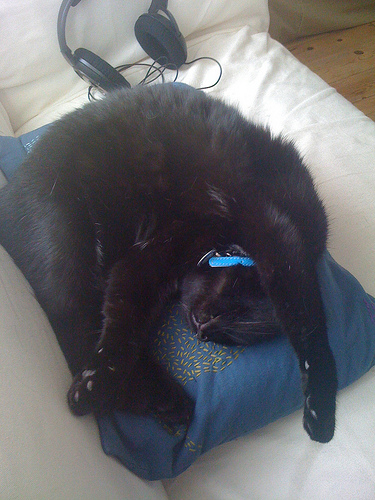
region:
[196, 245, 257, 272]
the blue collar on the cat's neck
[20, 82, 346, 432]
the black cat laying on the pillow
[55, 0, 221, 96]
the headphones sitting on the couch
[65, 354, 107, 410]
a paw of the cat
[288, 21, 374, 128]
the floor by the couch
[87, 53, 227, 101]
the wires attached to the headphones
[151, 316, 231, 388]
the yellow pattern on the pillow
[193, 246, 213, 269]
the tag on the collar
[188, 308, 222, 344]
the mouth and nose of the kitty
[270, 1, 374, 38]
a rug on the floor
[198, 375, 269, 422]
blue pillow that cat is laying on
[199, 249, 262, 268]
blue collar cat is wearing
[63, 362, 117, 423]
paws of the cat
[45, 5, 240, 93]
black headphones on the bed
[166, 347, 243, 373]
decoration on the pillow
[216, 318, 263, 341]
whiskers on the cat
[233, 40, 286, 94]
white sheet on the bed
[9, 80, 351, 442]
black cat laying on the pillow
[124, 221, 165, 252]
white hairs on the cat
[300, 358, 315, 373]
claw on the cat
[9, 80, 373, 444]
a kitty on a pillow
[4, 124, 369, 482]
the pillow is blue with yellow stitching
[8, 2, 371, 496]
white sheets are on the bed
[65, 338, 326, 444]
the cat has black pads on the paws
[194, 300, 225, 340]
the cat's canine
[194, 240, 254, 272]
the cat has a blue collar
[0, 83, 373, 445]
the kitty has all black fur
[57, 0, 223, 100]
a head set is on the bed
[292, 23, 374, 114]
the floor in the room is wooden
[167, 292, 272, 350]
the cat's whiskers are black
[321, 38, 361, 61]
this is the floor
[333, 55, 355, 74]
the floor is wooden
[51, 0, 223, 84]
these are some headphones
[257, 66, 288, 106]
this is a bed sheet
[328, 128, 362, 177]
the sheet is white in color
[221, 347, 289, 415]
this is a pillow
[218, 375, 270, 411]
the pillow is blue in color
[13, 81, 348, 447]
this is a cat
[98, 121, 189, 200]
the fur is black in color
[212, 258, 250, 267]
the collar is blue in color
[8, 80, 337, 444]
an upside down kitty cat on a pillow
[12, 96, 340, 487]
the cat is on a blue pillow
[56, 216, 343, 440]
the kitty is sleeping soundly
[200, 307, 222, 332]
a canine tooth is protruding from the mouth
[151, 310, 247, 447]
a yellow design is on the pillow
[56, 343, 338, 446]
the pads on the paws are black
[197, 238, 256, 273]
the cat has a blue collar on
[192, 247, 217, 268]
a tag is on the collar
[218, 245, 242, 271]
a buckle is on the collar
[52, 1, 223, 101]
a pair of headsets are on the bed